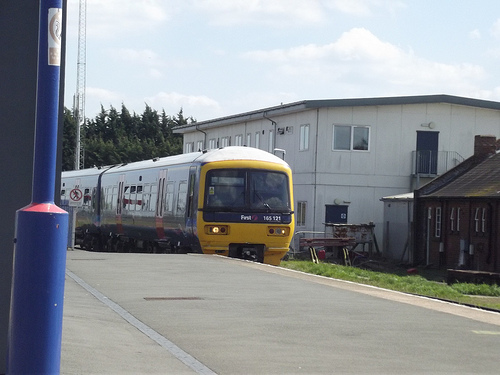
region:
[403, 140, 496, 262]
brown house with brown roof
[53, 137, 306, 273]
yellow and grey train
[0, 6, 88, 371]
blue and red post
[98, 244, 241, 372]
grey concrete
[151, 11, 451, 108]
blue sky with clouds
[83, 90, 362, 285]
train passing a building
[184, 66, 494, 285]
train next to a white building and brown building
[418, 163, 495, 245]
brown building with white windows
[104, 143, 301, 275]
train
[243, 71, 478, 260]
white building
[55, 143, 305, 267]
train at station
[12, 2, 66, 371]
blue pole in foreground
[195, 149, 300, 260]
yellow paint on front of train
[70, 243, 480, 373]
grey concrete station platform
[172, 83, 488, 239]
light colored building behind train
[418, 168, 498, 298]
brown building next to light colored building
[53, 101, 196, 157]
many trees in background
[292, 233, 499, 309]
green grass next to buildings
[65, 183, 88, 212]
no pedestrians sign next to tracks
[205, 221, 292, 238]
headlights lit on train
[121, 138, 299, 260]
A train pulling into the station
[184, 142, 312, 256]
A yellow front on the train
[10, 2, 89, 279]
A blue post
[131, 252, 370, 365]
An empty platform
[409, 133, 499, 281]
A brown building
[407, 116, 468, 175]
A door opening onto a balcony with stairs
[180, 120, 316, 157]
A row of windows in a second story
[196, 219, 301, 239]
Headlights on the train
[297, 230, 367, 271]
A sawhorse next to a building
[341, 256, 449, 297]
A swathe of green grass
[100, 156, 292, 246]
One train is reaching the station.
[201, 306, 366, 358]
Pavement is grey color.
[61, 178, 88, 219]
One signal board is in the pavement.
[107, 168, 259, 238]
Train is yellow and blue color.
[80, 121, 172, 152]
Trees are behind the train.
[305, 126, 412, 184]
Building is white color.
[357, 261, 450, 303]
Grass is green color.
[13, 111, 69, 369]
Pole is blue color.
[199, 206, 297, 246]
Lights are on in front of the train.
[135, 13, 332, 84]
Clouds are white color.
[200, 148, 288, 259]
the yellow front end of a train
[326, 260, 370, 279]
grass on the side of the road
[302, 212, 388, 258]
wooden laundry equipment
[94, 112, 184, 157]
the green top of trees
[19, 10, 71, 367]
a blue pole near the street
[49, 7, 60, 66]
a red and white sticker on the pole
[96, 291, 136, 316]
a white line in the middle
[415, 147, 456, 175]
a metal railing on the building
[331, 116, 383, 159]
the window in a small apartment building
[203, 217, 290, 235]
lit headlights on the train